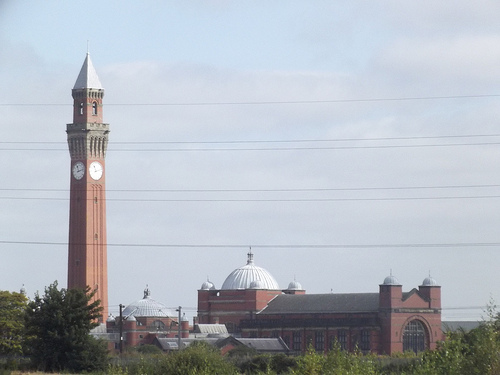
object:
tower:
[64, 47, 111, 337]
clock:
[86, 161, 105, 183]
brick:
[87, 226, 92, 236]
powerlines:
[0, 239, 499, 251]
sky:
[1, 0, 499, 272]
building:
[192, 242, 309, 334]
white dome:
[202, 246, 296, 292]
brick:
[227, 304, 235, 310]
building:
[105, 282, 190, 355]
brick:
[125, 321, 136, 328]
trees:
[17, 278, 107, 374]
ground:
[5, 353, 499, 374]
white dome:
[121, 287, 174, 318]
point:
[70, 48, 102, 89]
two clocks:
[68, 160, 107, 182]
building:
[236, 266, 457, 361]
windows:
[360, 329, 374, 351]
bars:
[360, 337, 368, 347]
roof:
[211, 331, 289, 352]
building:
[211, 333, 294, 360]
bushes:
[379, 312, 497, 373]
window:
[401, 319, 430, 353]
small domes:
[380, 273, 401, 286]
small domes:
[197, 278, 218, 292]